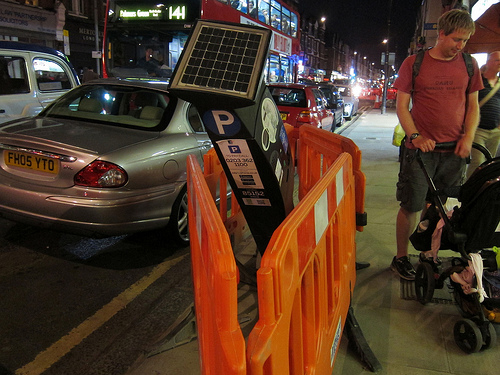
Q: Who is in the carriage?
A: Baby.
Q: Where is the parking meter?
A: To the left of the man.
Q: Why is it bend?
A: It is broken.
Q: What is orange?
A: Fence.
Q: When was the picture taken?
A: Nighttime.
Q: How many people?
A: Two.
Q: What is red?
A: Shirt.